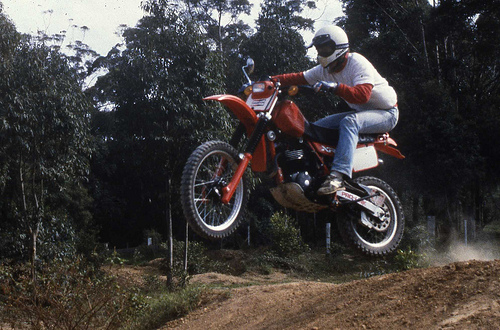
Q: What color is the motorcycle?
A: Red.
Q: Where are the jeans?
A: On the rider.